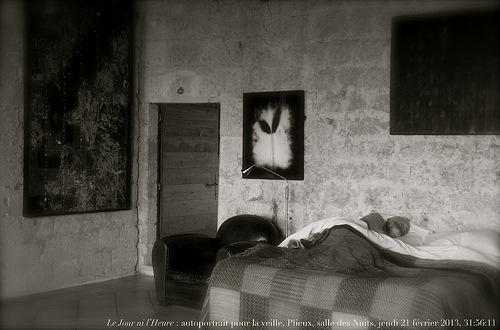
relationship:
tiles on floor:
[51, 290, 148, 324] [3, 273, 215, 328]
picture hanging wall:
[230, 81, 314, 180] [145, 8, 497, 302]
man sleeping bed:
[359, 212, 409, 238] [204, 176, 484, 321]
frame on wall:
[234, 80, 312, 191] [144, 29, 478, 262]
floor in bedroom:
[17, 270, 145, 328] [8, 15, 476, 325]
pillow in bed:
[426, 224, 499, 259] [189, 195, 484, 316]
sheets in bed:
[346, 195, 483, 287] [286, 212, 479, 266]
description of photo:
[106, 315, 499, 329] [0, 0, 497, 328]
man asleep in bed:
[303, 211, 410, 272] [206, 226, 497, 328]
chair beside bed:
[149, 215, 275, 309] [194, 208, 498, 326]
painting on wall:
[25, 6, 132, 210] [109, 37, 186, 267]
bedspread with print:
[200, 223, 498, 328] [262, 270, 322, 313]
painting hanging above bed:
[388, 12, 498, 134] [212, 194, 497, 321]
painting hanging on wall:
[244, 94, 304, 177] [254, 56, 351, 111]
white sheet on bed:
[275, 213, 497, 273] [194, 208, 498, 326]